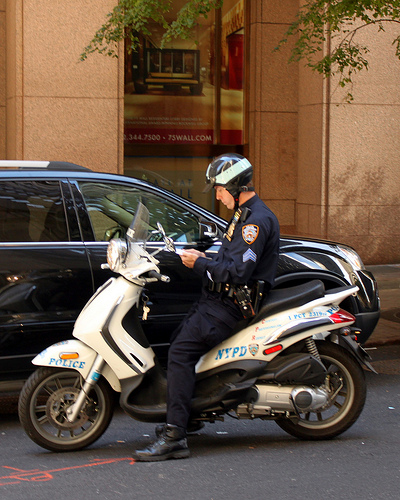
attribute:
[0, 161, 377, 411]
car — black 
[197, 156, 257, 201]
safety helmet — black , white 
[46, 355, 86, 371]
word — police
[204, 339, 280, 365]
sticker — city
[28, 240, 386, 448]
scooter — white 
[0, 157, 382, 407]
suv — black 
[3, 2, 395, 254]
building — brown 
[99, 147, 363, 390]
officer — police officer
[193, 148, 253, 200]
helmet — White , black 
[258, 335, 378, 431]
tire — bike, back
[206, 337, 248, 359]
letters — blue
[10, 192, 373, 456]
scooter — white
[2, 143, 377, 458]
officer — police officer